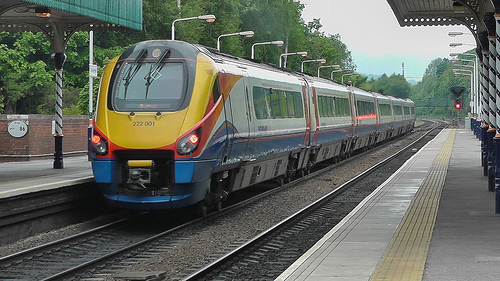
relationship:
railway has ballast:
[0, 119, 463, 281] [256, 191, 339, 251]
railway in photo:
[61, 206, 243, 271] [1, 0, 483, 275]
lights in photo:
[175, 21, 362, 90] [1, 0, 483, 275]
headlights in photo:
[88, 131, 202, 147] [1, 0, 483, 275]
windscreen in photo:
[111, 56, 189, 108] [1, 0, 483, 275]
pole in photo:
[23, 19, 90, 168] [1, 0, 483, 275]